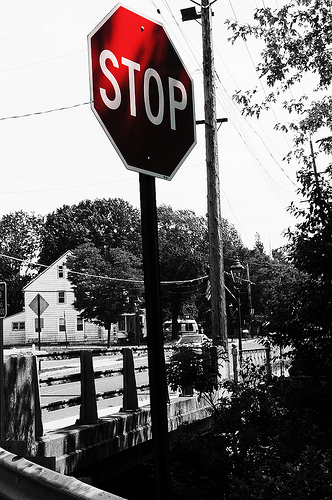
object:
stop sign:
[86, 1, 197, 180]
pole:
[138, 170, 172, 498]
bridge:
[2, 343, 295, 472]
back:
[28, 295, 50, 316]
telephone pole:
[189, 0, 228, 351]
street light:
[229, 254, 245, 376]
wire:
[1, 101, 92, 122]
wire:
[228, 0, 296, 158]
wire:
[260, 1, 304, 122]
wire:
[0, 253, 208, 284]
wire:
[223, 269, 258, 285]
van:
[162, 319, 199, 340]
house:
[21, 249, 120, 346]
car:
[173, 333, 213, 355]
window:
[58, 290, 66, 304]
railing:
[36, 345, 178, 362]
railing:
[39, 364, 149, 387]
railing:
[40, 382, 150, 412]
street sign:
[34, 317, 44, 330]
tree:
[64, 243, 146, 348]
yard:
[2, 344, 147, 353]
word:
[99, 49, 188, 132]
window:
[57, 264, 65, 278]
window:
[76, 319, 84, 332]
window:
[58, 317, 68, 335]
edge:
[68, 244, 139, 258]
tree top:
[65, 242, 147, 329]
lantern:
[229, 256, 245, 286]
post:
[236, 284, 244, 374]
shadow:
[5, 349, 217, 459]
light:
[5, 344, 269, 454]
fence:
[5, 344, 232, 439]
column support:
[0, 353, 44, 440]